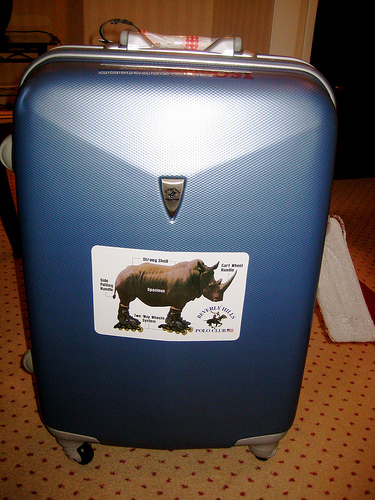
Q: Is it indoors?
A: Yes, it is indoors.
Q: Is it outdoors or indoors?
A: It is indoors.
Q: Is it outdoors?
A: No, it is indoors.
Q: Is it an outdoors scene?
A: No, it is indoors.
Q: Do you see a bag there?
A: Yes, there is a bag.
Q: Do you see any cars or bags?
A: Yes, there is a bag.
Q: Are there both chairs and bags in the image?
A: No, there is a bag but no chairs.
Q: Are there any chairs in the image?
A: No, there are no chairs.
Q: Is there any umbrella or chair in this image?
A: No, there are no chairs or umbrellas.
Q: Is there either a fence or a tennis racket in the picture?
A: No, there are no fences or rackets.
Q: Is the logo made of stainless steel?
A: Yes, the logo is made of stainless steel.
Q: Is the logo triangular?
A: Yes, the logo is triangular.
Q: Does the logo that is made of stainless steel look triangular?
A: Yes, the logo is triangular.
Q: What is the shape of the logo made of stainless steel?
A: The logo is triangular.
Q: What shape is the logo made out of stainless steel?
A: The logo is triangular.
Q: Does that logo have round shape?
A: No, the logo is triangular.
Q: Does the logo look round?
A: No, the logo is triangular.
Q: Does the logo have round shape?
A: No, the logo is triangular.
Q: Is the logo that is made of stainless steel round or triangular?
A: The logo is triangular.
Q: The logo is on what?
A: The logo is on the bag.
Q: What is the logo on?
A: The logo is on the bag.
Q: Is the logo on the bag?
A: Yes, the logo is on the bag.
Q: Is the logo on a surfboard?
A: No, the logo is on the bag.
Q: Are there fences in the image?
A: No, there are no fences.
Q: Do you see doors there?
A: Yes, there is a door.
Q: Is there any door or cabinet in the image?
A: Yes, there is a door.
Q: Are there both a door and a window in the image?
A: No, there is a door but no windows.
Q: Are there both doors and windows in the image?
A: No, there is a door but no windows.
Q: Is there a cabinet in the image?
A: No, there are no cabinets.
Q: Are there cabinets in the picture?
A: No, there are no cabinets.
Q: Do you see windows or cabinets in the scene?
A: No, there are no cabinets or windows.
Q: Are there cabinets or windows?
A: No, there are no cabinets or windows.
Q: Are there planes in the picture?
A: No, there are no planes.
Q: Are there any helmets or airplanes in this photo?
A: No, there are no airplanes or helmets.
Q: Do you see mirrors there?
A: No, there are no mirrors.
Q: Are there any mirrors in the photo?
A: No, there are no mirrors.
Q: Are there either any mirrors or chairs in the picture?
A: No, there are no mirrors or chairs.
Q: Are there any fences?
A: No, there are no fences.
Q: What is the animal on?
A: The animal is on the sticker.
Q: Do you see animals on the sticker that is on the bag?
A: Yes, there is an animal on the sticker.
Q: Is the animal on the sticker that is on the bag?
A: Yes, the animal is on the sticker.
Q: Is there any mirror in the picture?
A: No, there are no mirrors.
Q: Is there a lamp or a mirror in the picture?
A: No, there are no mirrors or lamps.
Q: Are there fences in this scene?
A: No, there are no fences.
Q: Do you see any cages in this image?
A: No, there are no cages.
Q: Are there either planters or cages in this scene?
A: No, there are no cages or planters.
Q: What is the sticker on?
A: The sticker is on the bag.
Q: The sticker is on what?
A: The sticker is on the bag.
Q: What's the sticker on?
A: The sticker is on the bag.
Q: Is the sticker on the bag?
A: Yes, the sticker is on the bag.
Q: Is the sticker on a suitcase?
A: No, the sticker is on the bag.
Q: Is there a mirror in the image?
A: No, there are no mirrors.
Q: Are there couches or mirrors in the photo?
A: No, there are no mirrors or couches.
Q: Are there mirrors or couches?
A: No, there are no mirrors or couches.